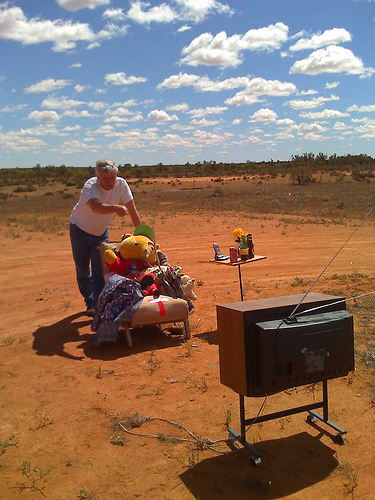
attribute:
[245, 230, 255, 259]
beer bottle — brown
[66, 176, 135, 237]
shirt — white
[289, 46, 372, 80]
clouds — white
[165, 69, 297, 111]
clouds — white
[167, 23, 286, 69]
clouds — white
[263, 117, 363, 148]
clouds — white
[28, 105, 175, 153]
clouds — white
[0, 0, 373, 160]
sky — blue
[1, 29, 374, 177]
sky — amazing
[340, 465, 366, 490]
grass — small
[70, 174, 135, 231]
white shirt — plain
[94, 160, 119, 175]
hair — gray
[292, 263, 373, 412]
grass — patchy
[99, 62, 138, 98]
cloud — small, white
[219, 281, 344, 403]
television — square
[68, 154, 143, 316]
man — standing up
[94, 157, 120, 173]
hair — white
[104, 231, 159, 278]
bear — stuffed, large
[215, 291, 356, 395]
television — black and brown